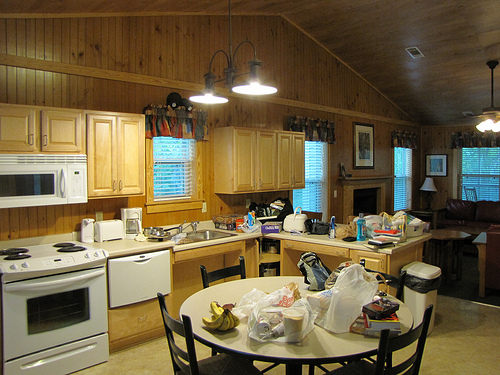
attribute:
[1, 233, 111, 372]
stove — white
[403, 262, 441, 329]
garbage can — white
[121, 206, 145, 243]
coffee maker — white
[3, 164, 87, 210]
microwave — white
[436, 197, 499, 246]
sofa — brown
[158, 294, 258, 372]
chair — wooden, black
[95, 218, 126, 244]
toaster — white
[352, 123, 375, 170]
picture — framed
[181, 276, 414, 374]
kitchen table — brown, white, round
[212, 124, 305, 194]
cupboards — brown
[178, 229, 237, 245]
sink — stainless steel, silver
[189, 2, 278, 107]
light fixtures — on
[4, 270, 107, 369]
oven — white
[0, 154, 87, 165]
microwave range hood — whie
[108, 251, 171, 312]
dishwasher — white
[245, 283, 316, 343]
plastic bag — white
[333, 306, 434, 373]
chair — black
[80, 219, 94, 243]
can opener — white